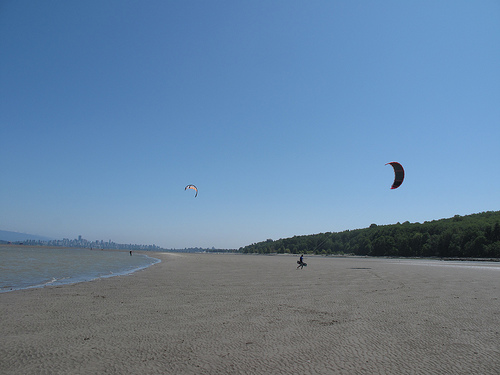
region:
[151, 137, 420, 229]
tow kites flying in the sky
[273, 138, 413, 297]
a person flying a kite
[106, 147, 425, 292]
two people flying kites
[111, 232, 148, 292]
a person standing in the water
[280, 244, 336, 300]
a person standing on a beach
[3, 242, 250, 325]
a beach next to the ocean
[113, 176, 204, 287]
a kite in the sky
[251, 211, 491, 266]
a line of trees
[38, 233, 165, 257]
a sky line of a city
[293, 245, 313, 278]
a person carrying a surf board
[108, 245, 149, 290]
water coming ashore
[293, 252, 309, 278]
surfer carrying a surfboard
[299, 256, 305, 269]
surfer is wearing a wet suit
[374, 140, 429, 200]
kite in the sky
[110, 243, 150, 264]
person in the water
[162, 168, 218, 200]
kite is flying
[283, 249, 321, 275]
surfer walking in the sand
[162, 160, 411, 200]
two kites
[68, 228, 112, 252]
buildings on the other side of the water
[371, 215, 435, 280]
trees at the edge of the sand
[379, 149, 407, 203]
kite in the sky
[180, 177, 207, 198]
kite flying in the sky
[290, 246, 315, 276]
person walking on the sand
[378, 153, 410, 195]
kite is curled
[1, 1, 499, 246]
bright blue sky with no clouds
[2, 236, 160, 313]
water rolling into shore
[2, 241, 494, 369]
shore is covered in sand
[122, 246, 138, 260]
person standing in the water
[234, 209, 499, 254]
thick, dark green trees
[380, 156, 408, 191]
black kite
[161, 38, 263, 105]
blue sky above the land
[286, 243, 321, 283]
person on the beach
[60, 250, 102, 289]
water next to shore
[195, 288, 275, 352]
marks on the sand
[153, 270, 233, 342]
sand on the beach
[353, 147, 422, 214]
object in the air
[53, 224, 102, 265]
buildings in the background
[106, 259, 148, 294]
water and sand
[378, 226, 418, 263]
trees next to the beach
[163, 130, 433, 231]
two objects in the sky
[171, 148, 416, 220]
two kites in the sky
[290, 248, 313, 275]
a person walks on the sand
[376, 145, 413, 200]
a C-kite on the sky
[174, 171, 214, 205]
a C-kite on blue sky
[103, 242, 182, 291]
a person stands in the water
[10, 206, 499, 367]
green trees on side the beach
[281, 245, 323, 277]
person walks to the right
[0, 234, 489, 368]
two people in the beach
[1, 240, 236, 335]
ocean water on the sand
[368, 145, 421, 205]
kite shaped like half moon